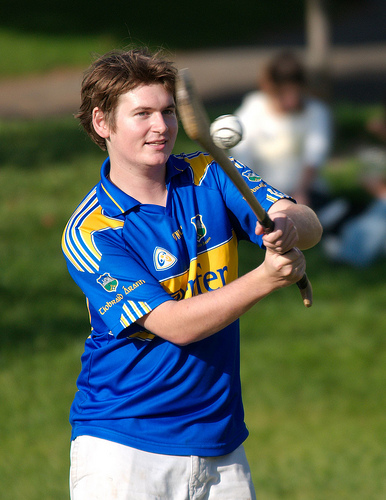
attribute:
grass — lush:
[266, 322, 385, 466]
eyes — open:
[135, 106, 175, 119]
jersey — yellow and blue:
[59, 151, 297, 455]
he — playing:
[59, 46, 323, 498]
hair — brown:
[70, 45, 179, 148]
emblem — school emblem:
[84, 254, 135, 317]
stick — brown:
[176, 73, 333, 259]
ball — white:
[201, 111, 254, 158]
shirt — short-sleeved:
[51, 147, 296, 456]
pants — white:
[66, 409, 270, 496]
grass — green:
[0, 25, 381, 498]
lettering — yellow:
[165, 264, 231, 303]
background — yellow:
[158, 232, 240, 305]